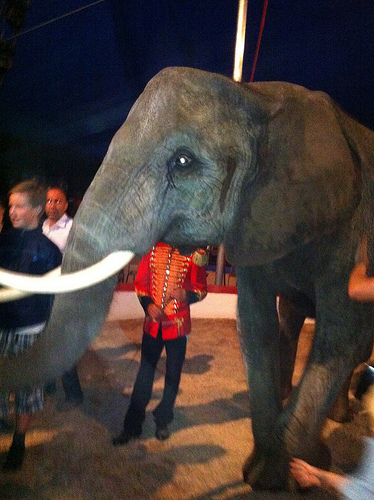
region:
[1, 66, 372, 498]
People around a large elephant.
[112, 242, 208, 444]
A man wearing an ornate uniform.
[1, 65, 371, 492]
A large elephant with tusks.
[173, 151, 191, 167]
Light is reflecting on the elephant's eye.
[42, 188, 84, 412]
A bald man in a white shirt.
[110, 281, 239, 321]
A low wall with a red border.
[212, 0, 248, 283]
A large metal pole.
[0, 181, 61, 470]
A teenager wearing a jacket and shorts.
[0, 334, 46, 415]
A pair of plaid shorts.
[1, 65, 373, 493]
A person is touching the elephant.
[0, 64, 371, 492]
An elephant at a circus.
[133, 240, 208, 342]
An orange jacket on a man.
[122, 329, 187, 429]
Pants on a man.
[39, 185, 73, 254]
A man in a white shirt.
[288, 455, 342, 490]
Blurry arms and hands.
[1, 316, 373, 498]
Dirt in an arena.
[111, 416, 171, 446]
A pair of blurry shoes.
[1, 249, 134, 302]
An elephants two tusks.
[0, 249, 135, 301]
Two ivory tusks.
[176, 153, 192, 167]
An elephants eye ball.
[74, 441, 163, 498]
The ground is brown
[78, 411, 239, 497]
The shadows are on the ground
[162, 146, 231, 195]
The elephant's eye is open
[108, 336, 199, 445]
The man has dark pants on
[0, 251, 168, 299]
The tusks are white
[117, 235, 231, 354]
The man has a red coat on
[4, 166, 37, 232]
The boy is smiling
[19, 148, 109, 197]
It is dark out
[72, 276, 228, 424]
The man is standing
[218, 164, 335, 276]
The elephant is gray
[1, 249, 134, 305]
elepehant has two tusks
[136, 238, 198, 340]
the uniform is red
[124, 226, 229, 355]
the uniform is red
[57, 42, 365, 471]
a full grown adult elephant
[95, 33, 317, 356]
the head of an elephant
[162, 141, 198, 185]
the eyes of an elephant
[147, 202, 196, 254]
the mouth of an elephant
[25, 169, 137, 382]
the trunk of an elephant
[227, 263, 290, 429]
the right leg of an elephant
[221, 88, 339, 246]
the ear of an elephant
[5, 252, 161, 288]
The elephant has turk.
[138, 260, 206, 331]
A person in a red jacket.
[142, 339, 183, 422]
The man is wearing black pants.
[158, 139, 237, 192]
The eye of the elephant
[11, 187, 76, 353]
A boy standing by the elephant.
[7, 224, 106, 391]
The trunk of the elephant.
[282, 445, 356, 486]
A hand of a person.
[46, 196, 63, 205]
The man is wearing glasses.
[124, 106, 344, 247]
The elephant is gray.